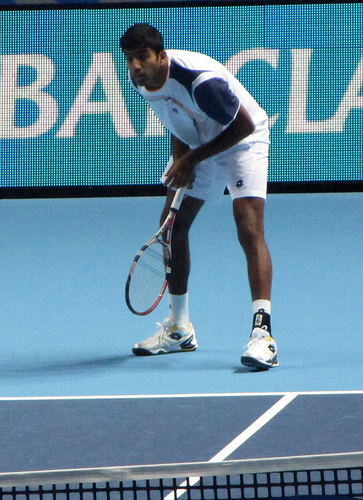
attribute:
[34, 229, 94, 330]
court — blue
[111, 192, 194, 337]
racket — white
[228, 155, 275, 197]
shorts — white